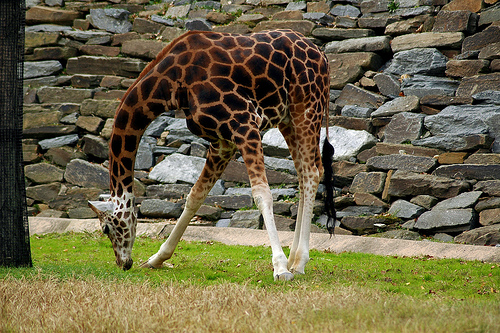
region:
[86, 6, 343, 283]
Giraffe on the grass.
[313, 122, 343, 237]
black hair on the tail.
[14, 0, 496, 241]
Stone wall in the background.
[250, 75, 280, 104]
Brown spot on the giraffe.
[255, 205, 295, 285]
white leg on the giraffe.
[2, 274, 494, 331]
brown grass in the forefront.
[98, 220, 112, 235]
black eye on the giraffe.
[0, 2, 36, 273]
Black netting by the giraffe.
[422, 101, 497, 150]
Gray rock in the wall.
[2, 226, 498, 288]
Green grass on the ground.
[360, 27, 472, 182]
Stone fence in the zebra enclosure.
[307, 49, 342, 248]
Long tail on the zebra.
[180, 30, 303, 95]
Brown spots on the zebra.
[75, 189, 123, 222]
Only one ear can be seen.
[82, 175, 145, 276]
Zebra may eat some green grass.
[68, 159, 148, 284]
head of a giraffe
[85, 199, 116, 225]
ear of a giraffe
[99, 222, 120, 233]
nose of a giraffe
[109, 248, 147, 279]
mouth of a giraffe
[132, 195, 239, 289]
leg of a giraffe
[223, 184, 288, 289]
leg of a giraffe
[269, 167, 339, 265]
leg of a giraffe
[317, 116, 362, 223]
tail of a giraffe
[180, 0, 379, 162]
body of a giraffe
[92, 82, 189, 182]
a neck of a giraffe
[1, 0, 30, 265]
mesh cover on tree trunk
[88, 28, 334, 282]
standing giraffe bending over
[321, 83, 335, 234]
black hair on tail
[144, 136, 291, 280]
two spread giraffe legs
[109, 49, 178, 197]
bent neck of giraffe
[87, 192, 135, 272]
giraffe head on grass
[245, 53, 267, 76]
brown spot on fur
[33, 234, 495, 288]
surface of green grass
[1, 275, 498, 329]
tall dried yellow grass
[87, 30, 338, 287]
the giraffe is bent over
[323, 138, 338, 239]
the hair is black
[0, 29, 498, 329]
the giraffe is on the grass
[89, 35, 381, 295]
the giraffe is bending over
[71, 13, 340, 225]
the giraffe is red and brown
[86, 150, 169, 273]
the head is white and brown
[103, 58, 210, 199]
the neck is long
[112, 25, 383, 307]
the giraffe is standing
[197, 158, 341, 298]
the legs are spread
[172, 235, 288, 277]
the grass is mowed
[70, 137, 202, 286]
the giraffe is grazing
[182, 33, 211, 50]
spot is on back of giraffe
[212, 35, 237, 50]
spot is on back of giraffe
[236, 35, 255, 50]
spot is on back of giraffe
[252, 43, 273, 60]
spot is on back of giraffe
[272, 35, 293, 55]
spot is on back of giraffe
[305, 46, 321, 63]
spot is on back of giraffe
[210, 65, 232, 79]
spot is on back of giraffe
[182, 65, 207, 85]
spot is on back of giraffe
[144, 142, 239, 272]
leg belongs to giraffe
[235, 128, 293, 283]
leg belongs to giraffe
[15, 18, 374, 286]
animal on the grass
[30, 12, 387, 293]
animal with a bent kneck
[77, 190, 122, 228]
ear of the giraffe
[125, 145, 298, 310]
front legs of the giraffe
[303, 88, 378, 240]
tail of the giraffe